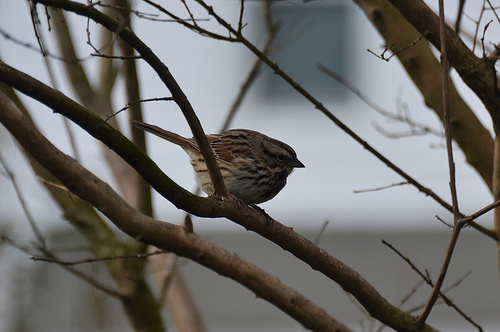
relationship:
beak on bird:
[290, 158, 305, 169] [102, 94, 294, 213]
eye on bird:
[268, 142, 295, 168] [169, 80, 329, 219]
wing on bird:
[209, 130, 260, 172] [128, 100, 311, 215]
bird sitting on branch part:
[127, 118, 305, 227] [195, 195, 290, 242]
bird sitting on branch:
[127, 118, 305, 227] [7, 82, 402, 322]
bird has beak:
[127, 118, 305, 227] [285, 154, 310, 174]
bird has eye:
[127, 118, 305, 227] [272, 149, 289, 165]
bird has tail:
[127, 118, 305, 227] [128, 114, 198, 161]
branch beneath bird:
[0, 0, 500, 330] [144, 117, 301, 209]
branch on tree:
[0, 0, 500, 330] [4, 1, 484, 324]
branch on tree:
[0, 58, 440, 330] [4, 1, 484, 324]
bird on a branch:
[132, 122, 304, 199] [3, 186, 426, 311]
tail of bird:
[127, 116, 191, 152] [127, 118, 305, 227]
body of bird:
[186, 128, 277, 202] [127, 112, 307, 229]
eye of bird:
[275, 153, 286, 163] [127, 112, 307, 229]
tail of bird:
[127, 111, 192, 152] [127, 118, 305, 227]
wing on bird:
[209, 133, 260, 168] [131, 117, 306, 196]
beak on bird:
[290, 155, 305, 171] [127, 118, 305, 227]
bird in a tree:
[127, 118, 305, 227] [4, 1, 484, 324]